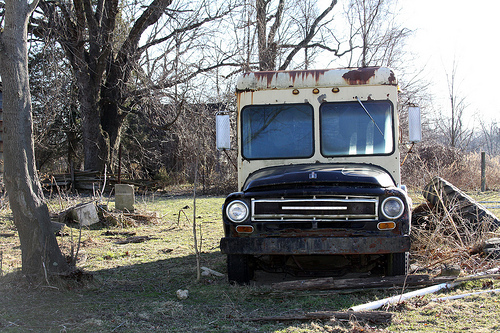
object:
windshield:
[318, 98, 396, 155]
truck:
[225, 65, 414, 279]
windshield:
[239, 101, 316, 159]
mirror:
[408, 106, 423, 144]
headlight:
[381, 195, 405, 220]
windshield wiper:
[353, 95, 386, 138]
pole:
[347, 267, 496, 313]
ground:
[0, 198, 464, 331]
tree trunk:
[0, 0, 72, 280]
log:
[267, 273, 433, 291]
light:
[374, 219, 398, 230]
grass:
[144, 288, 175, 321]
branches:
[283, 0, 416, 64]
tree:
[252, 0, 294, 74]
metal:
[355, 71, 370, 84]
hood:
[247, 164, 391, 187]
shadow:
[0, 258, 410, 332]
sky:
[0, 0, 499, 136]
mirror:
[216, 114, 231, 148]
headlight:
[225, 199, 251, 224]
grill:
[254, 194, 380, 222]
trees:
[0, 0, 419, 286]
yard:
[1, 167, 230, 320]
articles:
[237, 269, 471, 333]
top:
[233, 65, 398, 91]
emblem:
[307, 170, 320, 181]